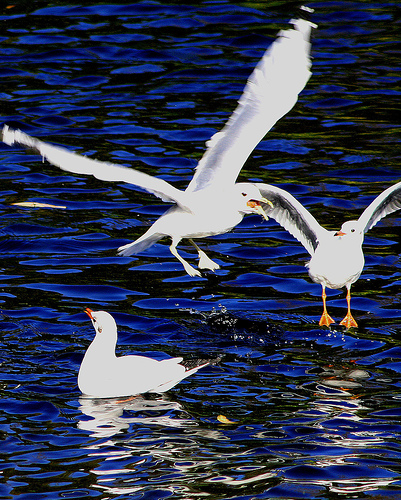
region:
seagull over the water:
[24, 28, 312, 259]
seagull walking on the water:
[247, 168, 383, 344]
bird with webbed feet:
[315, 309, 362, 332]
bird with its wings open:
[232, 174, 398, 234]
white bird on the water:
[75, 300, 201, 400]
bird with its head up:
[63, 294, 127, 351]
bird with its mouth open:
[244, 188, 273, 223]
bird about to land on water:
[172, 236, 222, 283]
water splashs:
[179, 278, 243, 329]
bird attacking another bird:
[180, 166, 365, 297]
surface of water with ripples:
[3, 3, 398, 495]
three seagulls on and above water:
[5, 4, 399, 400]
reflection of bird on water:
[293, 352, 392, 491]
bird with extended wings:
[4, 7, 316, 275]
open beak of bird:
[245, 197, 273, 221]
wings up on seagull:
[260, 182, 399, 289]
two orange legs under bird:
[319, 285, 359, 327]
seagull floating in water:
[78, 307, 212, 399]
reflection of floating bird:
[82, 395, 202, 497]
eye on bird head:
[349, 227, 357, 233]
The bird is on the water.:
[74, 307, 208, 405]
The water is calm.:
[13, 436, 92, 496]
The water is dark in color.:
[10, 410, 106, 496]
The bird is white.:
[77, 304, 203, 421]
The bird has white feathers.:
[77, 303, 205, 408]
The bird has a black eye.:
[89, 314, 101, 323]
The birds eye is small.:
[88, 315, 101, 324]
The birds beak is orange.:
[82, 301, 120, 334]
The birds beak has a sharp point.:
[83, 302, 120, 339]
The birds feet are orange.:
[319, 288, 357, 329]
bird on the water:
[55, 264, 198, 413]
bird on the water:
[42, 284, 262, 442]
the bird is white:
[46, 290, 190, 416]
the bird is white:
[37, 274, 243, 461]